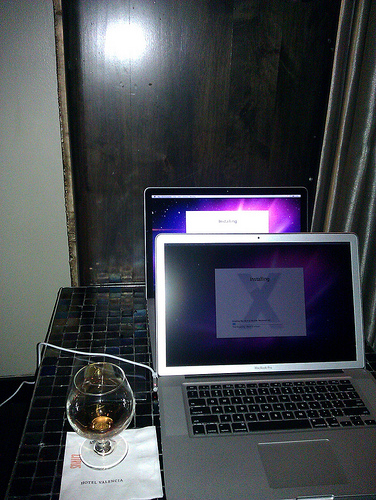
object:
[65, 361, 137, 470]
glass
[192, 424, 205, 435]
key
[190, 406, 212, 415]
key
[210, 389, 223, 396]
key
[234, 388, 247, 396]
key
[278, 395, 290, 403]
key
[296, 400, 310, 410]
key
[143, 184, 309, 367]
laptop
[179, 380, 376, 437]
keyboard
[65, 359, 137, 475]
cup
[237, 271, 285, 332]
x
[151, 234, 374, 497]
laptop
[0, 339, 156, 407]
cable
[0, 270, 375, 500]
table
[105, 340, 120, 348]
bricks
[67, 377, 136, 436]
liquid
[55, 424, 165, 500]
napkin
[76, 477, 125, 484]
valencia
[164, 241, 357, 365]
monitor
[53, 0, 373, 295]
wood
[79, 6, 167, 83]
reflection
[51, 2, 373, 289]
door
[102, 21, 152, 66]
light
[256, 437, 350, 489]
touch pad